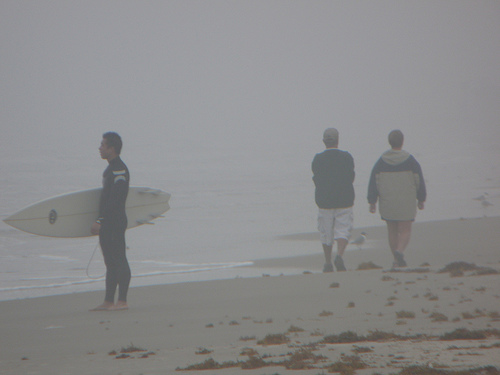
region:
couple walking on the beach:
[285, 96, 441, 276]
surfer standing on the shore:
[28, 133, 208, 345]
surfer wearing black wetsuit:
[76, 144, 160, 325]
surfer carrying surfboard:
[3, 182, 183, 242]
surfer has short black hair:
[97, 122, 144, 154]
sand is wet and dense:
[226, 258, 454, 370]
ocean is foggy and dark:
[147, 109, 354, 341]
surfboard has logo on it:
[38, 206, 83, 238]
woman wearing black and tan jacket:
[360, 140, 446, 240]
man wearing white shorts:
[316, 197, 356, 267]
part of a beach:
[339, 285, 356, 289]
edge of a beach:
[250, 290, 262, 308]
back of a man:
[331, 178, 350, 199]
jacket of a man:
[401, 203, 413, 221]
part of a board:
[159, 199, 168, 208]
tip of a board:
[19, 213, 23, 224]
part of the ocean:
[210, 220, 230, 247]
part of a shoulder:
[117, 175, 121, 219]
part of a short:
[326, 205, 342, 227]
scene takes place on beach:
[7, 8, 498, 372]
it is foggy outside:
[10, 8, 475, 127]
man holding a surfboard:
[35, 114, 215, 331]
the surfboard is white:
[4, 165, 224, 245]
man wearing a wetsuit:
[89, 158, 149, 306]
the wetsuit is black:
[86, 155, 157, 346]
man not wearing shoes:
[70, 276, 140, 316]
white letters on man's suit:
[107, 162, 137, 191]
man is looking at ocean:
[69, 99, 172, 329]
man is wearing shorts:
[315, 189, 364, 251]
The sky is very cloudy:
[46, 13, 477, 123]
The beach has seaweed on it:
[28, 308, 478, 368]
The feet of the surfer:
[88, 285, 133, 315]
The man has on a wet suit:
[85, 128, 136, 315]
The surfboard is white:
[3, 183, 177, 241]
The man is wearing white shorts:
[313, 199, 357, 250]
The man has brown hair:
[94, 130, 126, 162]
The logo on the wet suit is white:
[111, 165, 128, 187]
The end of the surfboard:
[133, 182, 173, 229]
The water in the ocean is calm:
[173, 133, 273, 241]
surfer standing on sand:
[6, 125, 179, 313]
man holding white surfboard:
[4, 129, 177, 320]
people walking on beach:
[302, 124, 433, 275]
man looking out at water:
[91, 127, 138, 314]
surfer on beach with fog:
[9, 128, 176, 374]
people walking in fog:
[306, 125, 428, 282]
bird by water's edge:
[352, 229, 373, 255]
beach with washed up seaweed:
[89, 319, 498, 372]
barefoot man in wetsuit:
[92, 126, 135, 313]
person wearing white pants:
[308, 125, 360, 276]